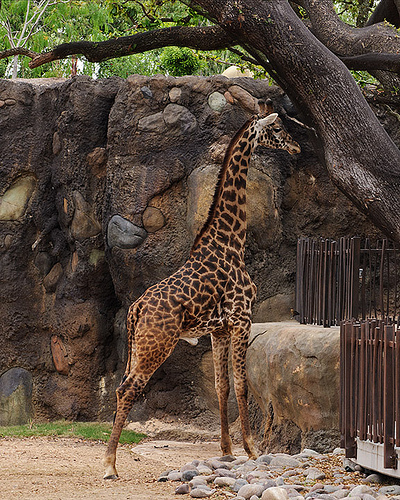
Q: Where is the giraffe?
A: On the dirt.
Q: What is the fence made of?
A: Metal.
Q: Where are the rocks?
A: In front of the fence.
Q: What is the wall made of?
A: Rocks.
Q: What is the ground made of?
A: Dirt and grass.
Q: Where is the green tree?
A: Behind the fence.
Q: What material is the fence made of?
A: Iron.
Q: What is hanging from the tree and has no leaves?
A: Branch.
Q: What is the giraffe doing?
A: Standing.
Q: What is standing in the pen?
A: Giraffe.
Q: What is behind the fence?
A: Tree.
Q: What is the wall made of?
A: Stone.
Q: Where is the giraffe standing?
A: By the tree.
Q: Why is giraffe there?
A: It is resting.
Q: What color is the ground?
A: Light brown.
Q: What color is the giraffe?
A: Black and brown.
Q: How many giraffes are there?
A: One.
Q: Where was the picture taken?
A: The zoo.